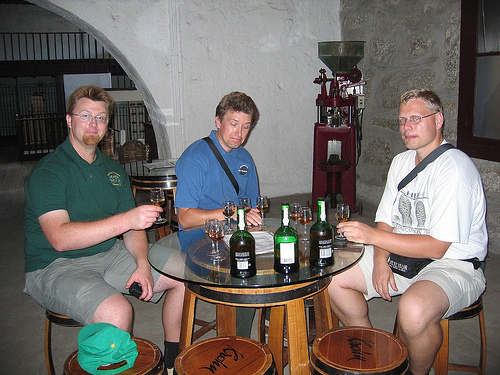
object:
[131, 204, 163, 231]
hand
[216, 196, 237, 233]
glass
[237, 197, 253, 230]
glass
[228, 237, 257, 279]
drink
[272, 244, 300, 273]
drink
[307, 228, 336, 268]
drink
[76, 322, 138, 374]
baseball hat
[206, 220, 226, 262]
glass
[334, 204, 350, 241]
glass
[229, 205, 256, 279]
bottle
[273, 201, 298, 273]
bottle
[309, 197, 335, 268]
bottle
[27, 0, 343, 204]
wall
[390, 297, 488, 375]
stool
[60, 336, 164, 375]
stool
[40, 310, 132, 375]
stool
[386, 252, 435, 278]
fanny pack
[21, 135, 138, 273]
shirt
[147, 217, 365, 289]
edge table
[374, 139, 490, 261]
shirt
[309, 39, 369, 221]
machine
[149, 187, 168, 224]
glass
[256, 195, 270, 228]
glass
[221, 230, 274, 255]
white paper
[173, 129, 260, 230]
shirt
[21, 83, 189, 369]
he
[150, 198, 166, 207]
wine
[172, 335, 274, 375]
stool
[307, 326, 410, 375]
stool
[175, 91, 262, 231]
man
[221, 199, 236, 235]
glass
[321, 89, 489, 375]
man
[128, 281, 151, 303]
object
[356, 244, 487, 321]
short